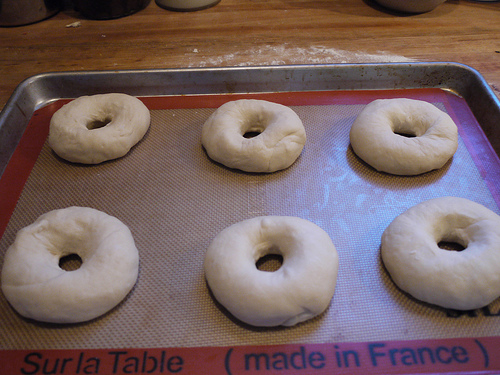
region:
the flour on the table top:
[178, 23, 418, 66]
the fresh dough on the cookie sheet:
[3, 207, 138, 329]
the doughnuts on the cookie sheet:
[1, 98, 497, 322]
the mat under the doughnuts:
[1, 100, 498, 373]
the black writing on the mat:
[18, 334, 498, 372]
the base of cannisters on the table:
[1, 3, 460, 26]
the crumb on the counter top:
[63, 18, 83, 27]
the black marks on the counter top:
[6, 28, 154, 68]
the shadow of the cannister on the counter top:
[269, 0, 376, 22]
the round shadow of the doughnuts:
[340, 174, 466, 191]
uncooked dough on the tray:
[3, 49, 499, 374]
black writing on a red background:
[236, 338, 473, 373]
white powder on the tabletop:
[173, 36, 424, 66]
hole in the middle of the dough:
[248, 239, 285, 274]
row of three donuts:
[4, 196, 499, 326]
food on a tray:
[2, 63, 499, 373]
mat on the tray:
[3, 89, 499, 374]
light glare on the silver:
[34, 99, 48, 106]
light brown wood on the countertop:
[2, 5, 499, 83]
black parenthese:
[222, 347, 239, 374]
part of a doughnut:
[247, 285, 276, 332]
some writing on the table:
[20, 336, 492, 373]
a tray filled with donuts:
[0, 70, 498, 372]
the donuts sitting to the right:
[357, 94, 495, 319]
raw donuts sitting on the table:
[18, 98, 498, 324]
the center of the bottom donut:
[248, 234, 288, 279]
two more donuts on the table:
[44, 91, 312, 181]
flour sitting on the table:
[183, 37, 413, 67]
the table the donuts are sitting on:
[8, 8, 493, 60]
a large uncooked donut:
[3, 205, 150, 327]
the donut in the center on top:
[200, 95, 307, 170]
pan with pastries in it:
[17, 44, 447, 373]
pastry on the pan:
[206, 208, 348, 327]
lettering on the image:
[29, 335, 474, 369]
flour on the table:
[210, 33, 387, 63]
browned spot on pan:
[370, 69, 439, 86]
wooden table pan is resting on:
[46, 19, 462, 58]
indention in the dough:
[26, 208, 85, 245]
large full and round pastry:
[379, 185, 499, 300]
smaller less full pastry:
[194, 91, 302, 166]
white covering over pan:
[36, 100, 493, 344]